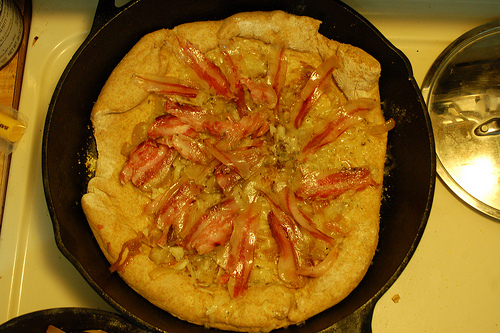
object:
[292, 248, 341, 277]
onions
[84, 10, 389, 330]
fajita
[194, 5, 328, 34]
crust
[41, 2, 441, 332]
skillet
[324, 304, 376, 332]
handle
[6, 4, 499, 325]
stove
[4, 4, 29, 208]
cabinet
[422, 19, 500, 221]
lid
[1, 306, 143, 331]
skillet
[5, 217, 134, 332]
corner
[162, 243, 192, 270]
cabbage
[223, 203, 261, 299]
bacon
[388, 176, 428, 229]
iron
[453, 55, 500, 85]
metal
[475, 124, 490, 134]
screw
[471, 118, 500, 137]
handle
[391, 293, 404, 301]
crumbs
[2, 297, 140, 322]
edge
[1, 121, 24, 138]
plastic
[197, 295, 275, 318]
golden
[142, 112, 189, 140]
sausage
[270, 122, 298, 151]
cheese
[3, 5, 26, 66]
jar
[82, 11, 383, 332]
cornbread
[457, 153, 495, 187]
reflection